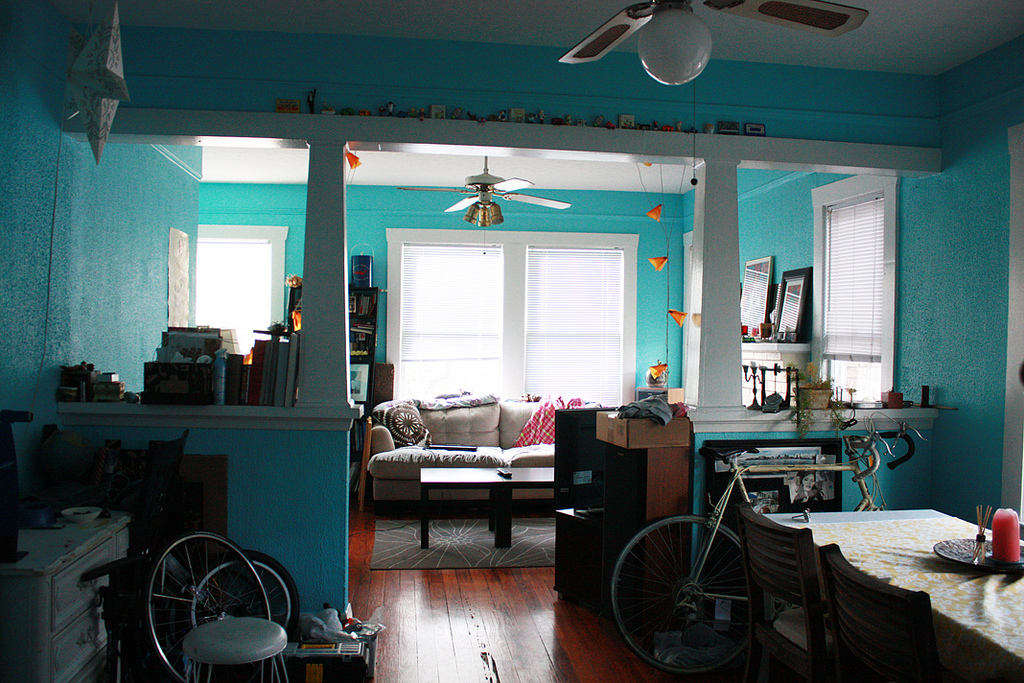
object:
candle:
[992, 508, 1021, 561]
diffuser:
[974, 504, 993, 563]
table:
[761, 509, 1024, 669]